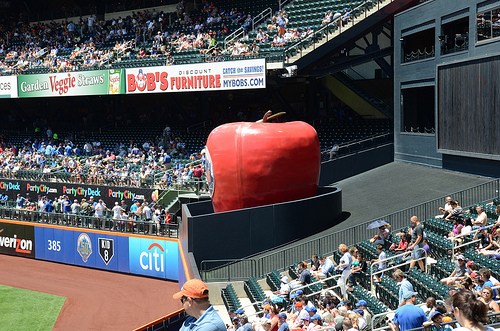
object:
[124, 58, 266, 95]
signs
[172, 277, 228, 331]
fan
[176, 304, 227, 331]
shirt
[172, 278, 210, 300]
cap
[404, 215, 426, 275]
fans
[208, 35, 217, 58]
fans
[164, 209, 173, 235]
fans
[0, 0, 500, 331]
stadium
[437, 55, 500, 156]
woodenplank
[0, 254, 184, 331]
baseball field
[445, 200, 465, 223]
person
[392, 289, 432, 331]
person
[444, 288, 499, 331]
person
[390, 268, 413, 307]
person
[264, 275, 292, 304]
spectators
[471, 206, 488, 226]
person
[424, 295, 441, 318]
person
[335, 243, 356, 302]
person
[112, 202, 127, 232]
person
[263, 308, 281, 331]
person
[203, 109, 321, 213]
apple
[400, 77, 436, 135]
closed window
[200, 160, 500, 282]
ground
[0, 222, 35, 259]
sponsor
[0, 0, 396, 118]
side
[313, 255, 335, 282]
person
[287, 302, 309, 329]
spectators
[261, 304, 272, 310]
caps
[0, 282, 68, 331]
grass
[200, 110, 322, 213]
bag